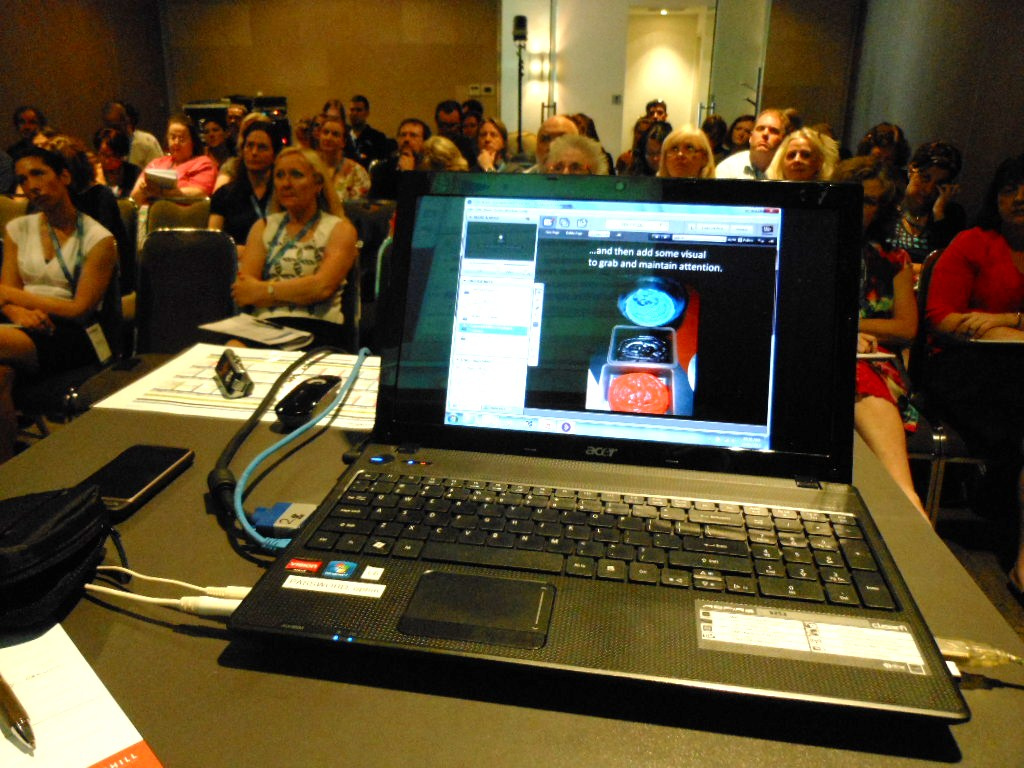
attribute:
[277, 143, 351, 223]
hair — blonde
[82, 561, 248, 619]
cord — white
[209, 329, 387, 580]
cord — blue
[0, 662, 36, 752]
pen — brown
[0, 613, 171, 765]
paper — white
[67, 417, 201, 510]
phone — silver, black, smart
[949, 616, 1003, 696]
cable — clear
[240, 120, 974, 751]
laptop — black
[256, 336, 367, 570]
ethernet cable — blue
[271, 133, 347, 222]
hair — gray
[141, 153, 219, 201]
shirt — coral colored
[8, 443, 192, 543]
phone — black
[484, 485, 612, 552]
keys — black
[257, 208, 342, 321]
shirt — white, sleeveless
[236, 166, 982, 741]
laptop — black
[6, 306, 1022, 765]
table — black